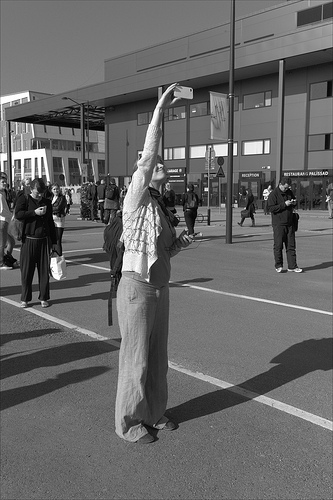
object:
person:
[113, 82, 194, 444]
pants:
[115, 272, 170, 443]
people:
[86, 177, 120, 224]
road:
[0, 201, 332, 500]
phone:
[173, 85, 193, 99]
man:
[267, 176, 303, 273]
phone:
[290, 200, 295, 203]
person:
[237, 188, 256, 227]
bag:
[241, 209, 251, 218]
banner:
[208, 91, 228, 141]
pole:
[225, 1, 235, 243]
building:
[3, 2, 331, 207]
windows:
[240, 139, 271, 156]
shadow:
[160, 336, 332, 423]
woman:
[14, 178, 57, 308]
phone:
[41, 205, 46, 212]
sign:
[282, 169, 329, 177]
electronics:
[174, 231, 203, 246]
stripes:
[0, 293, 332, 431]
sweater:
[120, 124, 180, 284]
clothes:
[266, 185, 298, 270]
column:
[87, 99, 89, 162]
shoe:
[138, 432, 158, 442]